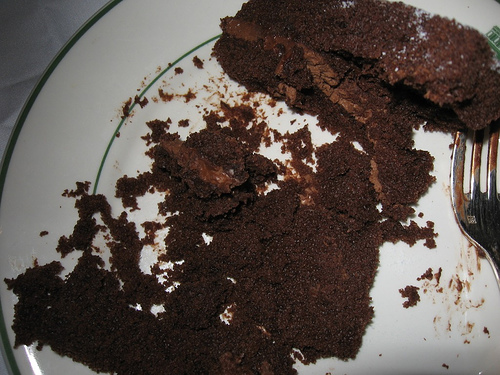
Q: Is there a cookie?
A: No, there are no cookies.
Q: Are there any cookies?
A: No, there are no cookies.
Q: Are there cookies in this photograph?
A: No, there are no cookies.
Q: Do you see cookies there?
A: No, there are no cookies.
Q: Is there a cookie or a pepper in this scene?
A: No, there are no cookies or peppers.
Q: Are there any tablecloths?
A: Yes, there is a tablecloth.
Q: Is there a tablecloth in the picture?
A: Yes, there is a tablecloth.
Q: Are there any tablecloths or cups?
A: Yes, there is a tablecloth.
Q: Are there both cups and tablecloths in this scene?
A: No, there is a tablecloth but no cups.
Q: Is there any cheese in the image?
A: No, there is no cheese.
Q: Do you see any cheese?
A: No, there is no cheese.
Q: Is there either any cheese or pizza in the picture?
A: No, there are no cheese or pizzas.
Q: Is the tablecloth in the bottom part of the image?
A: No, the tablecloth is in the top of the image.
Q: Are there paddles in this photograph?
A: No, there are no paddles.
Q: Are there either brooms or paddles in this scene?
A: No, there are no paddles or brooms.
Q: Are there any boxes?
A: No, there are no boxes.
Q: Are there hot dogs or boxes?
A: No, there are no boxes or hot dogs.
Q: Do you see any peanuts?
A: No, there are no peanuts.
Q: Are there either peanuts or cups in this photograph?
A: No, there are no peanuts or cups.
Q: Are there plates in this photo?
A: Yes, there is a plate.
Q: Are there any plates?
A: Yes, there is a plate.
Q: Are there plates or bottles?
A: Yes, there is a plate.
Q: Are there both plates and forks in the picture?
A: Yes, there are both a plate and a fork.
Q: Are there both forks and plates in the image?
A: Yes, there are both a plate and a fork.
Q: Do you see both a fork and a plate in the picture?
A: Yes, there are both a plate and a fork.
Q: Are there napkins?
A: No, there are no napkins.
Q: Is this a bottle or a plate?
A: This is a plate.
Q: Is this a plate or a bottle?
A: This is a plate.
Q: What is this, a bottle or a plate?
A: This is a plate.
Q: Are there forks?
A: Yes, there is a fork.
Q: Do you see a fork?
A: Yes, there is a fork.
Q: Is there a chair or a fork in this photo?
A: Yes, there is a fork.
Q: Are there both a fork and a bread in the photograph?
A: No, there is a fork but no breads.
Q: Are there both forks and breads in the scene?
A: No, there is a fork but no breads.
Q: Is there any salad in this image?
A: No, there is no salad.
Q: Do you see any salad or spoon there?
A: No, there are no salad or spoons.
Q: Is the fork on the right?
A: Yes, the fork is on the right of the image.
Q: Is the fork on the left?
A: No, the fork is on the right of the image.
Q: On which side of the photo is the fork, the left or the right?
A: The fork is on the right of the image.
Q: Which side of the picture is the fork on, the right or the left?
A: The fork is on the right of the image.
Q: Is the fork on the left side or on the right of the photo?
A: The fork is on the right of the image.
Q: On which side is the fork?
A: The fork is on the right of the image.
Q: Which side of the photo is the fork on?
A: The fork is on the right of the image.